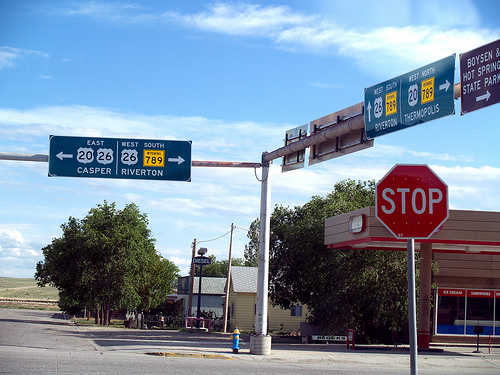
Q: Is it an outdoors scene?
A: Yes, it is outdoors.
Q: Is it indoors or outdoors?
A: It is outdoors.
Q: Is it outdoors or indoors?
A: It is outdoors.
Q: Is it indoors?
A: No, it is outdoors.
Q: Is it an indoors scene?
A: No, it is outdoors.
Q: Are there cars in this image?
A: No, there are no cars.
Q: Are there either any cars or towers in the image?
A: No, there are no cars or towers.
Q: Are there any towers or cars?
A: No, there are no cars or towers.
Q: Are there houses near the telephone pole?
A: Yes, there is a house near the telephone pole.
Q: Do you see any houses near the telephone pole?
A: Yes, there is a house near the telephone pole.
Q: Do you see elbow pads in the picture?
A: No, there are no elbow pads.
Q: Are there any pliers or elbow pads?
A: No, there are no elbow pads or pliers.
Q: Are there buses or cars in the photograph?
A: No, there are no buses or cars.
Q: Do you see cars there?
A: No, there are no cars.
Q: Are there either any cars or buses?
A: No, there are no cars or buses.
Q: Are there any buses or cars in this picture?
A: No, there are no cars or buses.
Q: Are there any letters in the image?
A: Yes, there are letters.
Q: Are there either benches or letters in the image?
A: Yes, there are letters.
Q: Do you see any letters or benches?
A: Yes, there are letters.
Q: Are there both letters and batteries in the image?
A: No, there are letters but no batteries.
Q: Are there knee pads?
A: No, there are no knee pads.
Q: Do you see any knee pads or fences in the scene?
A: No, there are no knee pads or fences.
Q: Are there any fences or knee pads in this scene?
A: No, there are no knee pads or fences.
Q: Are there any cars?
A: No, there are no cars.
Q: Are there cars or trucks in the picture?
A: No, there are no cars or trucks.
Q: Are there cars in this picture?
A: No, there are no cars.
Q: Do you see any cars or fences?
A: No, there are no cars or fences.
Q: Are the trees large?
A: Yes, the trees are large.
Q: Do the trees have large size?
A: Yes, the trees are large.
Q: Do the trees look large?
A: Yes, the trees are large.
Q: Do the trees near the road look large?
A: Yes, the trees are large.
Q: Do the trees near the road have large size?
A: Yes, the trees are large.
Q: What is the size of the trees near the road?
A: The trees are large.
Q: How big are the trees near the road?
A: The trees are large.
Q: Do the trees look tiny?
A: No, the trees are large.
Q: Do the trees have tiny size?
A: No, the trees are large.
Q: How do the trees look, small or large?
A: The trees are large.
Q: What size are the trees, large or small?
A: The trees are large.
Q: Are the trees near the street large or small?
A: The trees are large.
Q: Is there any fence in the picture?
A: No, there are no fences.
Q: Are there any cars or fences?
A: No, there are no fences or cars.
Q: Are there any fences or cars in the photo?
A: No, there are no fences or cars.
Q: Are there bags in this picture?
A: No, there are no bags.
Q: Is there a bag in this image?
A: No, there are no bags.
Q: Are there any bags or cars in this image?
A: No, there are no bags or cars.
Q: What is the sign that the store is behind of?
A: The sign is a stop sign.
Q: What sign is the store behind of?
A: The store is behind the stop sign.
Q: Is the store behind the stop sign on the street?
A: Yes, the store is behind the stop sign.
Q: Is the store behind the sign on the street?
A: Yes, the store is behind the stop sign.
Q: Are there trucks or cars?
A: No, there are no cars or trucks.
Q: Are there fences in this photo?
A: No, there are no fences.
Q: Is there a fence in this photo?
A: No, there are no fences.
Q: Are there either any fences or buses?
A: No, there are no fences or buses.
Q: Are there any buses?
A: No, there are no buses.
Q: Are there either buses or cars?
A: No, there are no buses or cars.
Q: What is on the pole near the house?
A: The sign is on the pole.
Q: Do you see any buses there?
A: No, there are no buses.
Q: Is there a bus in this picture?
A: No, there are no buses.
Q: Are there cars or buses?
A: No, there are no buses or cars.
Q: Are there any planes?
A: No, there are no planes.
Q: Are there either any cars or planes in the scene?
A: No, there are no planes or cars.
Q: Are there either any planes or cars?
A: No, there are no planes or cars.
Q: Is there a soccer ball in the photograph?
A: No, there are no soccer balls.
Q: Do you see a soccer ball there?
A: No, there are no soccer balls.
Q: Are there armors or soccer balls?
A: No, there are no soccer balls or armors.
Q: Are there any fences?
A: No, there are no fences.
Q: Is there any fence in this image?
A: No, there are no fences.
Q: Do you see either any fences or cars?
A: No, there are no fences or cars.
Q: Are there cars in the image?
A: No, there are no cars.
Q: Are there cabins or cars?
A: No, there are no cars or cabins.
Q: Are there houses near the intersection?
A: Yes, there is a house near the intersection.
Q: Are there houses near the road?
A: Yes, there is a house near the road.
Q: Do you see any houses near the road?
A: Yes, there is a house near the road.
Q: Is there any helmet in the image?
A: No, there are no helmets.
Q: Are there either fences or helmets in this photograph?
A: No, there are no helmets or fences.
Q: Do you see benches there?
A: No, there are no benches.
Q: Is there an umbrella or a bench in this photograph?
A: No, there are no benches or umbrellas.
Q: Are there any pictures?
A: No, there are no pictures.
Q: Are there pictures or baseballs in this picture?
A: No, there are no pictures or baseballs.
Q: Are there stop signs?
A: Yes, there is a stop sign.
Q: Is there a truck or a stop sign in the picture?
A: Yes, there is a stop sign.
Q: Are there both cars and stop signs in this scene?
A: No, there is a stop sign but no cars.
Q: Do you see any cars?
A: No, there are no cars.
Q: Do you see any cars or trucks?
A: No, there are no cars or trucks.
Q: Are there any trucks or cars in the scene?
A: No, there are no cars or trucks.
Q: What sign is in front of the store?
A: The sign is a stop sign.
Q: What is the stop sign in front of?
A: The stop sign is in front of the store.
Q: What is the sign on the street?
A: The sign is a stop sign.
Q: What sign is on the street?
A: The sign is a stop sign.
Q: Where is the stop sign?
A: The stop sign is on the street.